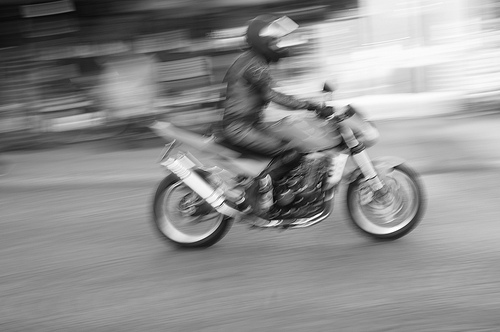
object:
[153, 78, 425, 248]
bike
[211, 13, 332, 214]
man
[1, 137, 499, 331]
road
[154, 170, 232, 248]
wheel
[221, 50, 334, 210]
outfit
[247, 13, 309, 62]
helmet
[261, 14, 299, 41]
visor